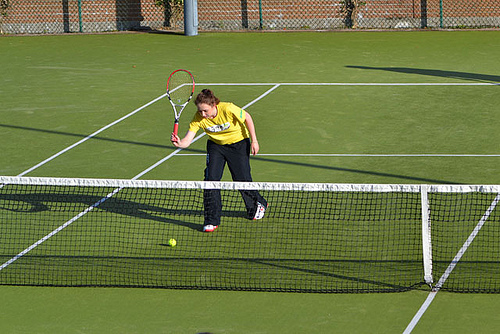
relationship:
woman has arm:
[172, 88, 269, 232] [173, 119, 202, 147]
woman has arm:
[172, 88, 269, 232] [225, 104, 260, 156]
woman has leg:
[172, 88, 269, 232] [228, 153, 269, 220]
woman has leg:
[172, 88, 269, 232] [203, 155, 227, 233]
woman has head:
[172, 88, 269, 232] [195, 88, 218, 120]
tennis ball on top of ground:
[166, 238, 176, 246] [0, 29, 499, 332]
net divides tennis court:
[0, 176, 499, 294] [0, 1, 498, 333]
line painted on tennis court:
[175, 151, 500, 159] [0, 1, 498, 333]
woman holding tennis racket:
[172, 88, 269, 232] [164, 69, 196, 144]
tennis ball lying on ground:
[166, 238, 176, 246] [0, 29, 499, 332]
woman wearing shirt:
[172, 88, 269, 232] [188, 102, 248, 145]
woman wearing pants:
[172, 88, 269, 232] [203, 140, 269, 226]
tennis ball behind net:
[166, 238, 176, 246] [0, 176, 499, 294]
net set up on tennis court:
[0, 176, 499, 294] [0, 1, 498, 333]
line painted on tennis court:
[0, 84, 265, 273] [0, 1, 498, 333]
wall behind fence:
[1, 1, 499, 35] [1, 1, 499, 27]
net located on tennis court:
[0, 176, 499, 294] [0, 1, 498, 333]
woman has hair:
[172, 88, 269, 232] [194, 88, 221, 108]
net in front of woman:
[0, 176, 499, 294] [172, 88, 269, 232]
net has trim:
[0, 176, 499, 294] [1, 174, 499, 193]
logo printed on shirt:
[203, 123, 230, 133] [188, 102, 248, 145]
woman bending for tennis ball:
[172, 88, 269, 232] [166, 238, 176, 246]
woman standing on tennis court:
[172, 88, 269, 232] [0, 1, 498, 333]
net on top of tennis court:
[0, 176, 499, 294] [0, 1, 498, 333]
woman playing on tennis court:
[172, 88, 269, 232] [0, 1, 498, 333]